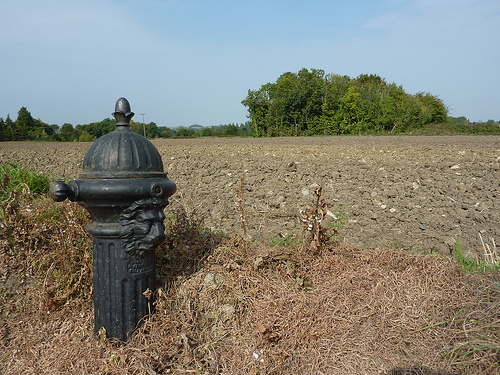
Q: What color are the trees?
A: Green.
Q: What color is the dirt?
A: Brown.